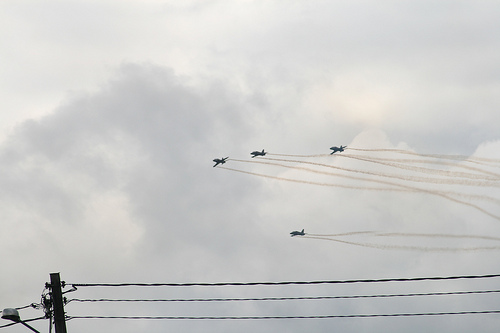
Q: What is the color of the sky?
A: White.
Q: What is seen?
A: Jet plane.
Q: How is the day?
A: Cloudy.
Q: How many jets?
A: 4.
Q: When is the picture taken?
A: Daytime.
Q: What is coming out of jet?
A: Smoke.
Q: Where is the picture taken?
A: Under planes.